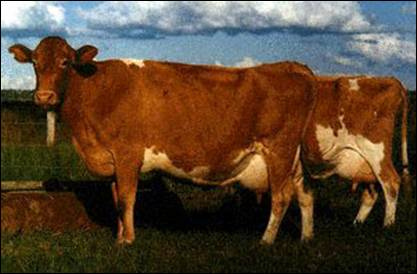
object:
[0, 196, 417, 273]
ground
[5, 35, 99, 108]
head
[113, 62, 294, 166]
side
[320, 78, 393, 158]
side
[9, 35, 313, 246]
cow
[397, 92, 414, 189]
cow tail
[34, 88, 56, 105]
nose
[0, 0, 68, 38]
clouds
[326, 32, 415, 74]
clouds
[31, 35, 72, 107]
face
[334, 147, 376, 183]
udder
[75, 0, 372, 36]
clouds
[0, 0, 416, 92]
sky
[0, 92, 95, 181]
fence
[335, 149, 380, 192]
utters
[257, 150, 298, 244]
back legs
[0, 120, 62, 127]
fencing wire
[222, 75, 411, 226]
cow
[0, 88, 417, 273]
pasture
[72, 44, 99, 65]
ear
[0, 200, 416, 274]
grass